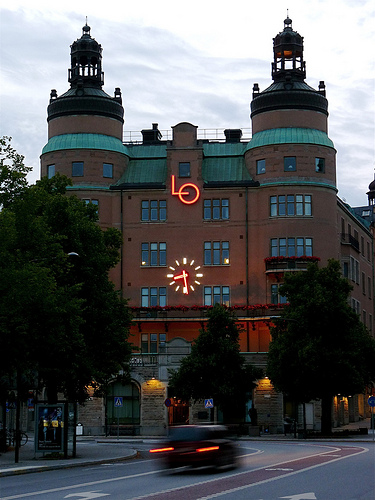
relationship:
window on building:
[138, 198, 168, 223] [21, 6, 372, 439]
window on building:
[150, 200, 159, 221] [21, 6, 372, 439]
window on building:
[201, 197, 212, 224] [21, 6, 372, 439]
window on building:
[220, 197, 228, 222] [21, 6, 372, 439]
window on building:
[252, 156, 269, 176] [43, 16, 368, 426]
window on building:
[281, 154, 297, 171] [21, 6, 372, 439]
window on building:
[313, 154, 328, 175] [21, 6, 372, 439]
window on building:
[174, 156, 195, 181] [43, 16, 368, 426]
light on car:
[193, 443, 219, 456] [145, 417, 243, 472]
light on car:
[151, 443, 175, 456] [145, 417, 243, 472]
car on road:
[149, 422, 238, 475] [2, 428, 369, 498]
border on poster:
[34, 401, 42, 449] [28, 394, 74, 458]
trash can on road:
[71, 417, 83, 438] [2, 428, 375, 497]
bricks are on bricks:
[147, 399, 158, 407] [147, 399, 158, 407]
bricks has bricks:
[147, 399, 158, 407] [147, 399, 158, 407]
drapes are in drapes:
[110, 391, 136, 420] [105, 383, 139, 425]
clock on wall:
[163, 251, 201, 293] [123, 192, 247, 307]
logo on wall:
[168, 171, 199, 204] [123, 158, 264, 306]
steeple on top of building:
[63, 17, 102, 88] [21, 6, 372, 439]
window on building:
[136, 280, 177, 308] [21, 6, 372, 439]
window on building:
[196, 282, 237, 308] [21, 6, 372, 439]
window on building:
[264, 276, 316, 310] [21, 6, 372, 439]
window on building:
[264, 235, 317, 258] [21, 6, 372, 439]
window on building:
[198, 235, 234, 269] [21, 6, 372, 439]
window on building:
[138, 242, 171, 271] [21, 6, 372, 439]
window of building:
[140, 200, 171, 221] [21, 6, 372, 439]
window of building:
[269, 195, 312, 216] [21, 6, 372, 439]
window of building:
[137, 330, 166, 354] [21, 6, 372, 439]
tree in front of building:
[168, 301, 261, 417] [21, 6, 372, 439]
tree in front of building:
[165, 301, 265, 433] [21, 6, 372, 439]